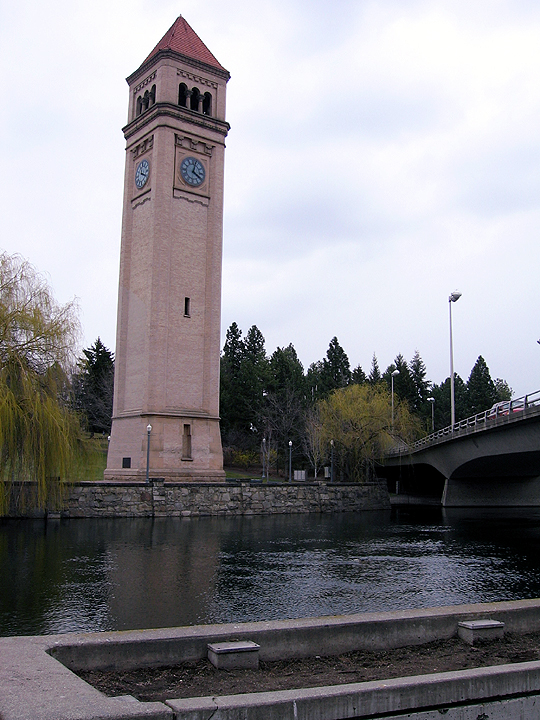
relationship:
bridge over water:
[402, 440, 510, 452] [299, 533, 459, 586]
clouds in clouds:
[5, 6, 539, 406] [0, 0, 540, 405]